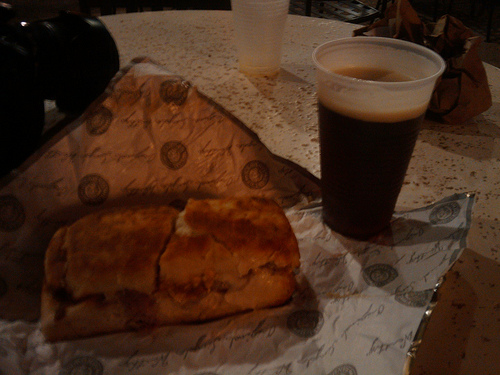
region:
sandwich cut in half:
[36, 194, 294, 339]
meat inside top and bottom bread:
[43, 273, 228, 307]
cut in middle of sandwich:
[147, 203, 187, 287]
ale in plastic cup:
[317, 66, 429, 228]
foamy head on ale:
[320, 65, 425, 119]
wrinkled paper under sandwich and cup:
[3, 58, 468, 370]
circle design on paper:
[362, 260, 399, 288]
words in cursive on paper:
[45, 143, 155, 162]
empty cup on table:
[232, 0, 294, 75]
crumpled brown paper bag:
[351, 3, 491, 121]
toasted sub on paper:
[45, 201, 296, 328]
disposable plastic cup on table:
[308, 39, 442, 236]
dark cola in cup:
[316, 98, 421, 239]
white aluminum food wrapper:
[7, 62, 471, 373]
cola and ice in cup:
[313, 38, 440, 237]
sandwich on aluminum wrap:
[31, 200, 305, 323]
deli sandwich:
[45, 204, 292, 322]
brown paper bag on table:
[353, 1, 492, 123]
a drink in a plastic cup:
[313, 38, 443, 234]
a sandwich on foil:
[39, 200, 302, 336]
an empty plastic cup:
[231, 0, 286, 77]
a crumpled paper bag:
[350, 3, 490, 123]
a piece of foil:
[3, 63, 473, 374]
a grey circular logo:
[158, 140, 188, 167]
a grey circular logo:
[286, 307, 324, 334]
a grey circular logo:
[362, 262, 397, 287]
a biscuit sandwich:
[44, 200, 298, 344]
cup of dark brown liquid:
[312, 38, 442, 237]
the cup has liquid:
[303, 55, 433, 257]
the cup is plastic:
[324, 83, 424, 228]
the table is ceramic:
[446, 145, 498, 198]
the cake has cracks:
[53, 209, 301, 319]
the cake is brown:
[46, 233, 296, 337]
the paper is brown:
[414, 12, 499, 102]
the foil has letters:
[328, 263, 421, 373]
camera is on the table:
[11, 10, 146, 115]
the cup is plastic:
[218, 8, 306, 76]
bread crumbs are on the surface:
[269, 83, 317, 155]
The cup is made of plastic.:
[313, 35, 445, 239]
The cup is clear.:
[311, 34, 445, 236]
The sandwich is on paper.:
[1, 56, 476, 373]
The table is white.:
[1, 8, 498, 373]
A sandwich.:
[38, 193, 307, 343]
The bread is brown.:
[37, 193, 298, 342]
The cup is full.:
[309, 35, 446, 237]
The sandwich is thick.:
[38, 195, 302, 340]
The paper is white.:
[3, 55, 475, 372]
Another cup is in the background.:
[230, 0, 290, 77]